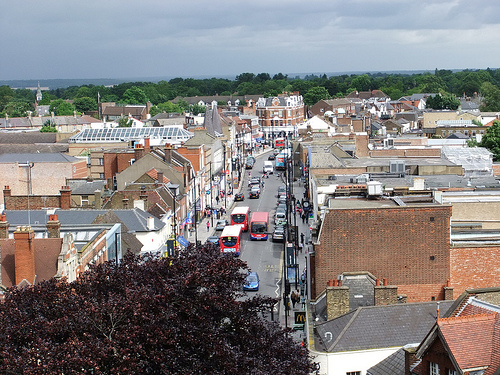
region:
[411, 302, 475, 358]
A roof is visible.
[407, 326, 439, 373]
A roof is visible.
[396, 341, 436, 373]
A roof is visible.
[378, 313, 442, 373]
A roof is visible.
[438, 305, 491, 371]
A roof is visible.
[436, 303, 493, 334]
A roof is visible.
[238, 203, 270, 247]
a red bus driving down a street.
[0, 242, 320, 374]
a tree with lots of purple leaves.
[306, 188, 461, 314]
a multi story brick building.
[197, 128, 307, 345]
a street with lots of traffic.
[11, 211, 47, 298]
a chimney on a building.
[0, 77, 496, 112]
a chimney on a building.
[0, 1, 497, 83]
a cloud filled sky.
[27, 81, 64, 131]
a tall church.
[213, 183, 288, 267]
three city buses on a street.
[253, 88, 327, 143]
a tall multi story building.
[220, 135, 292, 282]
buses moving along a narrow city street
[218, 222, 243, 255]
a city bus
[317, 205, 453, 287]
the roof of a building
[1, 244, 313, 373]
a large tree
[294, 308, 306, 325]
a golden arches sign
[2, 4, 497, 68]
a cloudy sky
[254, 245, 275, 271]
the street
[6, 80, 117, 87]
the ocean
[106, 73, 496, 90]
a grove of several trees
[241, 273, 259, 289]
a blue car driving down the street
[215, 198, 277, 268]
three busses on street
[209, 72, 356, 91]
green trees on horizon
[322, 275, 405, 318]
two chimneys on roof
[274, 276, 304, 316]
people walking on sidewalk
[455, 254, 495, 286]
building made of brick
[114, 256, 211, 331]
leaves on top of tree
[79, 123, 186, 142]
building with galss roog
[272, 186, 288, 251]
cars parrked on side of street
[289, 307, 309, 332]
yellow letter on sign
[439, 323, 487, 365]
red roof on building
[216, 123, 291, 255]
Red buses on the street.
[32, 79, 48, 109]
Church steeple in the background.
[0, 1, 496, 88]
Cloudy sky in the daytime.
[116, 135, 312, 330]
Poles up and down the street.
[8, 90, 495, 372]
Rooftops of many buildings.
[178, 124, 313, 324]
People walking on the street.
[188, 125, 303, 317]
Cars on the street.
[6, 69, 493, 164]
Trees in the background.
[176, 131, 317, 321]
Street signs up and down the street.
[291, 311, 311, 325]
Sign for McDonald's.